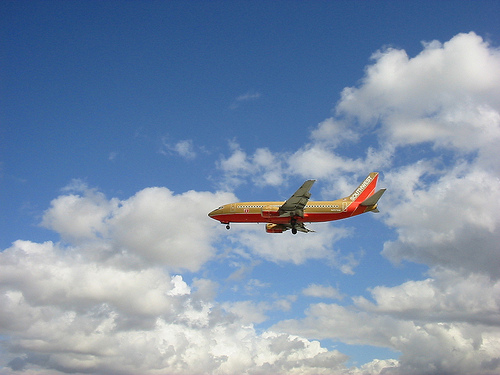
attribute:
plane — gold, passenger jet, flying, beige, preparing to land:
[208, 170, 389, 237]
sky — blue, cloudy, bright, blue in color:
[3, 5, 500, 371]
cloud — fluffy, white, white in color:
[309, 32, 499, 159]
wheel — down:
[288, 213, 300, 226]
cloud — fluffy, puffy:
[113, 184, 231, 265]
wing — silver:
[279, 173, 317, 224]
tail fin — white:
[344, 172, 386, 213]